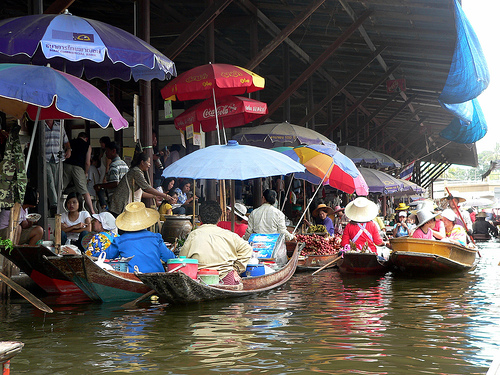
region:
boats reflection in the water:
[235, 288, 439, 352]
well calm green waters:
[175, 314, 337, 359]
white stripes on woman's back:
[338, 220, 390, 251]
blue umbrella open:
[149, 127, 299, 187]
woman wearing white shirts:
[51, 192, 94, 226]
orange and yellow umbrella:
[209, 50, 279, 100]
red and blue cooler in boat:
[148, 244, 225, 283]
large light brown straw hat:
[122, 194, 171, 241]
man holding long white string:
[292, 149, 379, 262]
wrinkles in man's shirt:
[259, 210, 313, 248]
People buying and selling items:
[0, 58, 499, 329]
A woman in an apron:
[100, 143, 181, 241]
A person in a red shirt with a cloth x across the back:
[344, 200, 387, 275]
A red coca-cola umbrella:
[167, 97, 269, 142]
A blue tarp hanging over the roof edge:
[440, 0, 490, 174]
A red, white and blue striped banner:
[393, 156, 427, 190]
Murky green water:
[123, 300, 487, 363]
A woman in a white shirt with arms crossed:
[54, 191, 92, 246]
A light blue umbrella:
[156, 137, 302, 233]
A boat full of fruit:
[299, 219, 341, 271]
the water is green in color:
[102, 305, 445, 369]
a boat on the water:
[391, 190, 484, 272]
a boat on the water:
[321, 237, 392, 278]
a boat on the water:
[142, 223, 321, 329]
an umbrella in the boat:
[140, 141, 310, 248]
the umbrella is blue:
[160, 132, 312, 206]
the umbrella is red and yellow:
[160, 55, 268, 104]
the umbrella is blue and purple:
[1, 58, 122, 180]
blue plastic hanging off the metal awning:
[425, 3, 490, 150]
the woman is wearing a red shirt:
[332, 216, 390, 253]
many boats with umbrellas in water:
[11, 14, 495, 348]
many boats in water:
[11, 21, 496, 361]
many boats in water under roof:
[17, 8, 454, 340]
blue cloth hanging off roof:
[422, 0, 497, 181]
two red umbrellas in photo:
[162, 44, 270, 158]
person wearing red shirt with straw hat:
[338, 195, 393, 269]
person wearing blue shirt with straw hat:
[88, 185, 193, 319]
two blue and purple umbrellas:
[8, 4, 183, 194]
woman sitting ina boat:
[32, 170, 110, 260]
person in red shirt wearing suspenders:
[324, 162, 401, 290]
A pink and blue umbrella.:
[1, 60, 129, 127]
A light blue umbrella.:
[161, 132, 309, 184]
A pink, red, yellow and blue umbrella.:
[294, 134, 368, 194]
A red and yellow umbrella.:
[152, 56, 276, 96]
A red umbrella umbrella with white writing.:
[166, 97, 276, 130]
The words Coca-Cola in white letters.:
[193, 99, 238, 120]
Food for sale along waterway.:
[288, 197, 344, 282]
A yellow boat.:
[383, 227, 484, 274]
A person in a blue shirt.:
[96, 200, 177, 280]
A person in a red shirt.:
[339, 193, 387, 260]